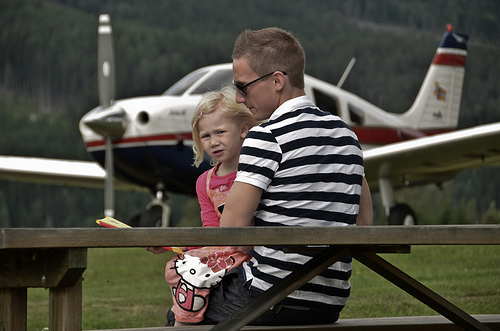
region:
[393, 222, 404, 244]
the bench is wooden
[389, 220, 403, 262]
the bench is wooden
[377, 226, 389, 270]
the bench is wooden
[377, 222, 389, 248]
the bench is wooden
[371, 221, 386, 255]
the bench is wooden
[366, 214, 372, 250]
the bench is wooden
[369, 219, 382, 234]
the bench is wooden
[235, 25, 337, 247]
this is a man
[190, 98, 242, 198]
this is a child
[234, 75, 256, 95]
he is wearing goggles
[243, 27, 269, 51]
the hair is short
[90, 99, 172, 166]
this is the plane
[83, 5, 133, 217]
this is the propeller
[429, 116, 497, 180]
this is the wing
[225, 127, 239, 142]
the child is light skinned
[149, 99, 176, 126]
the plane is white in color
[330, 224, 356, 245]
this is a board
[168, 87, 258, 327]
blonde girl in hello kitty dress sitting on a mans lap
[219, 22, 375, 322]
man in striped shirt holding a blonde girl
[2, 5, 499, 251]
airplane behind a girl an man sitting on a bench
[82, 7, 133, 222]
propeller on an airplane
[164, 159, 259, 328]
hello kitty dress on young blonde girl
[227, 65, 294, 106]
sunglasses on man in striped shirt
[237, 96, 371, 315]
striped shirt on man holding girl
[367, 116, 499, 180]
wing on airplane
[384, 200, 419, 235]
wheel on the airplane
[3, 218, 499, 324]
brown bench that girl and man are sitting on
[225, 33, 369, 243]
this is a man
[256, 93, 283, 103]
the man is light skinned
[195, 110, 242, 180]
this is a girl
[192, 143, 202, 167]
the hair is long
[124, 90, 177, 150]
this is a jet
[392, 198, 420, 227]
this is the wheel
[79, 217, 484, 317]
this is a bench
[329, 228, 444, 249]
the bench is wooden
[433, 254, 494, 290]
this is a grass area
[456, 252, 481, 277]
the grass is green in color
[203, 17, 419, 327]
man in striped shirt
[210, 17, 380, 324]
man in black sunglasses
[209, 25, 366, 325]
man with short hair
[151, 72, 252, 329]
little girl sitting on man's lap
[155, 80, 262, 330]
little girl with blonde hair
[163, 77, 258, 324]
little girl with pink Hello Kitty outfit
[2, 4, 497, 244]
large red white and blue airplane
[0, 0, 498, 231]
large metal aircraft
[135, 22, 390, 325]
two people sitting at a table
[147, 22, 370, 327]
two people sitting on a bench